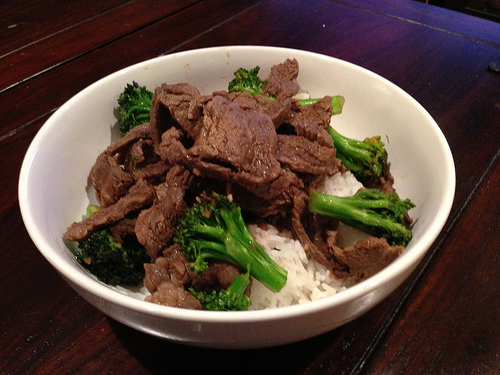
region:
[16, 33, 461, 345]
Bowl of asian food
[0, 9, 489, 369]
Dark wood table with bowl on it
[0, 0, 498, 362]
Cracks between boards on dark wood table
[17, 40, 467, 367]
White glass bowl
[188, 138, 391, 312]
Cooked white rice in bowl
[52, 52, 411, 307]
Pieces of steak in bowl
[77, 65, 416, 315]
Pieces of cooked broccoli in bowl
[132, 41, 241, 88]
Splatters of some kind of sauce on side of bowl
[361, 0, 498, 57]
Horizontal border around edge of wood table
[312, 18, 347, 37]
Small white spot on wood table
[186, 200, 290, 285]
a crunchy stalk of green broccoli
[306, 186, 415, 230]
a crunchy stalk of green broccoli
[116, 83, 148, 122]
a crunchy stalk of green broccoli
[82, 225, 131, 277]
a crunchy stalk of green broccoli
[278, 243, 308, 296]
grains of steamed white rice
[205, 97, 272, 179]
a succulent slice of beef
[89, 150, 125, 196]
a succulent slice of beef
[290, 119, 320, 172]
a succulent slice of beef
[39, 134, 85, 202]
a white ceramic bowl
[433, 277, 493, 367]
a dark brown wood table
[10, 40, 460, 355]
a bowl with food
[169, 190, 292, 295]
a broccoli on the dish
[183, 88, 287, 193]
a beef on the bowl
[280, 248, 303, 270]
rice on the bowl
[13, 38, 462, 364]
a rice bowl with broccoli and beef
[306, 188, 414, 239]
a broccoli on top of the beef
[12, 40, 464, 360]
a healthy meal on the bowl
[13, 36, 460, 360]
a healthy meal on the white bowl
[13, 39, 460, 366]
a white bowl with healthy food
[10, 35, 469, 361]
a delicious looking meal on a bowl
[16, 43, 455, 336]
Bowl of beef and broccoli over rice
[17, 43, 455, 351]
White bowl with food in it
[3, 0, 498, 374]
Dark colored hard wood table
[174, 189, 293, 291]
Green cooked broccoli spear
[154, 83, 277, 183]
Well done chunks of meat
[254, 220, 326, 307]
Fluffy white rice on the bottom of the bowl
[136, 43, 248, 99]
Juice from the meat splashed on the side of the bowl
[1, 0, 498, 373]
Stained wooden planks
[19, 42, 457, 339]
Traditional Chinese meal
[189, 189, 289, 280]
a piece of green color broccoli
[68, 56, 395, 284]
broccoli, rice and some eatables in the bowl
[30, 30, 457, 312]
white color ceramic bowl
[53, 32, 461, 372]
a bowl kept in the wooden table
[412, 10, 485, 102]
brown color wooden table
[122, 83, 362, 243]
many broccoli pieces in the bowl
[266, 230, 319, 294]
white color rice in the bowl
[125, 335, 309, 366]
shadow of the bowl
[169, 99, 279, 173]
brown color eatables in the bowl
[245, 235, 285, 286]
stem of the broccoli